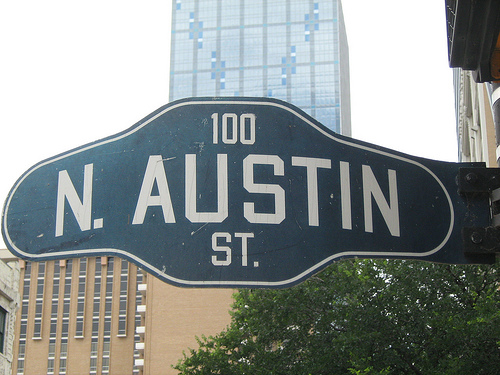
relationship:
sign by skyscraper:
[7, 73, 466, 314] [164, 6, 351, 190]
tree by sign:
[294, 249, 463, 374] [7, 73, 466, 314]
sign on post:
[7, 73, 466, 314] [460, 137, 499, 353]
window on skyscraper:
[53, 262, 122, 333] [164, 6, 351, 190]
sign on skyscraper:
[7, 73, 466, 314] [164, 6, 351, 190]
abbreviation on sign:
[206, 231, 258, 271] [7, 73, 466, 314]